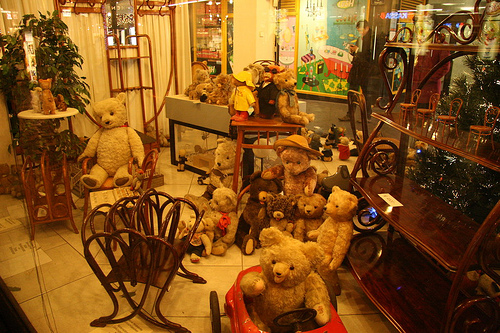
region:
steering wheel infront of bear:
[270, 309, 320, 322]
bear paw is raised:
[241, 276, 270, 296]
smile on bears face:
[268, 270, 288, 283]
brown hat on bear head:
[290, 139, 302, 146]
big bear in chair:
[83, 96, 140, 186]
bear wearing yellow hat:
[236, 74, 245, 77]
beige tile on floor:
[48, 270, 73, 290]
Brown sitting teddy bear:
[75, 94, 156, 191]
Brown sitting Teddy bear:
[238, 225, 336, 327]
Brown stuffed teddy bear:
[301, 188, 361, 283]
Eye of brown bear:
[109, 109, 117, 116]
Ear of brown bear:
[86, 100, 97, 108]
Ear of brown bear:
[116, 93, 132, 105]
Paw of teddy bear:
[70, 174, 104, 191]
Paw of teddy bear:
[111, 169, 133, 189]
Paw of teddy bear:
[248, 270, 270, 297]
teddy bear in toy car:
[203, 226, 346, 331]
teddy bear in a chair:
[76, 88, 156, 222]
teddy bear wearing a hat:
[267, 128, 324, 203]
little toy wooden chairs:
[392, 77, 495, 154]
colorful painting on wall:
[298, 2, 367, 101]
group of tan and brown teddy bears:
[182, 134, 354, 266]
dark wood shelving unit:
[345, 7, 494, 330]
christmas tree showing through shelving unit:
[421, 54, 496, 224]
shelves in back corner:
[187, 1, 229, 69]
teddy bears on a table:
[161, 58, 314, 141]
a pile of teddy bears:
[190, 145, 350, 258]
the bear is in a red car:
[211, 228, 343, 332]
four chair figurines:
[399, 89, 496, 147]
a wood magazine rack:
[23, 150, 77, 236]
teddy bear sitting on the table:
[274, 71, 314, 124]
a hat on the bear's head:
[273, 134, 325, 164]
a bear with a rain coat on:
[226, 67, 253, 122]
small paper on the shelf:
[378, 191, 400, 209]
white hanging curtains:
[136, 13, 171, 139]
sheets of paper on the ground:
[2, 238, 48, 280]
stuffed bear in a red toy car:
[209, 226, 342, 329]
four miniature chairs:
[395, 88, 499, 156]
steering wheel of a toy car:
[271, 306, 317, 327]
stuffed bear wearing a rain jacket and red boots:
[228, 70, 255, 125]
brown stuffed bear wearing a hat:
[266, 133, 318, 194]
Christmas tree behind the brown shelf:
[412, 146, 484, 192]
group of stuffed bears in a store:
[84, 68, 349, 328]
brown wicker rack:
[81, 187, 206, 330]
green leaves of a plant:
[0, 9, 87, 109]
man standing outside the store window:
[344, 19, 376, 123]